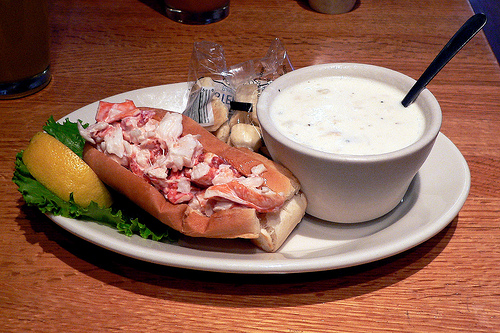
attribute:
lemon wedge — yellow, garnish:
[22, 131, 116, 220]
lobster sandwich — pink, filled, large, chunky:
[78, 95, 307, 255]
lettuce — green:
[14, 115, 184, 248]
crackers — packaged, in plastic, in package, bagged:
[191, 76, 268, 156]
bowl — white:
[255, 60, 442, 227]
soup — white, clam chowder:
[267, 76, 426, 159]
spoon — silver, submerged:
[400, 10, 489, 110]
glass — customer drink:
[0, 1, 54, 102]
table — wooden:
[2, 2, 500, 332]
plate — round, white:
[31, 77, 470, 275]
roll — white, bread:
[69, 91, 312, 259]